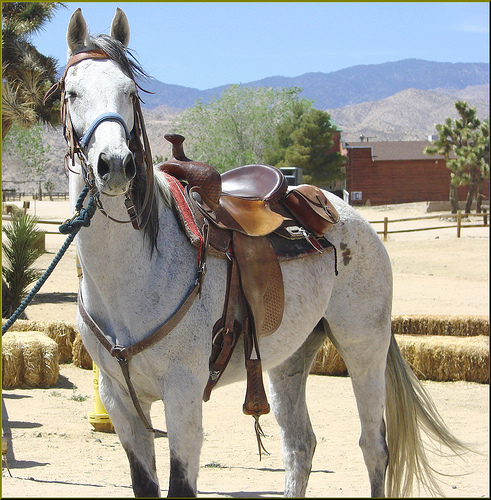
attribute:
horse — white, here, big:
[50, 4, 411, 494]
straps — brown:
[82, 214, 261, 451]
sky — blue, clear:
[4, 0, 489, 99]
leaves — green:
[189, 79, 301, 173]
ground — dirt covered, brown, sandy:
[1, 199, 488, 499]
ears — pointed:
[65, 4, 131, 52]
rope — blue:
[3, 112, 136, 348]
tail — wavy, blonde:
[382, 332, 470, 493]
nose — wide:
[93, 150, 138, 184]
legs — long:
[93, 329, 395, 494]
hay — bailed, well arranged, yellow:
[3, 291, 485, 395]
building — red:
[336, 128, 484, 208]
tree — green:
[434, 99, 490, 215]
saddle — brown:
[165, 133, 320, 416]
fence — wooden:
[8, 183, 487, 245]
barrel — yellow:
[83, 353, 143, 438]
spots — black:
[124, 451, 196, 499]